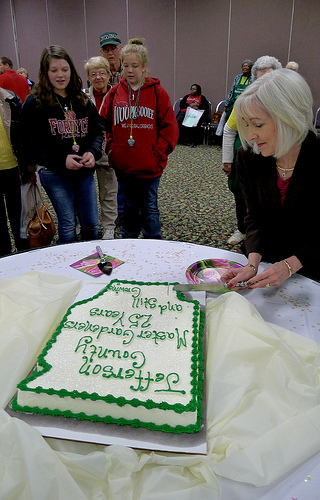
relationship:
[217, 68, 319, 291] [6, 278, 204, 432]
lady cutting cake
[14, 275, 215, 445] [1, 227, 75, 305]
cake on top of table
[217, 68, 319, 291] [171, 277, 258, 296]
lady holding knife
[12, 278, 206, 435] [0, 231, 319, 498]
cake on table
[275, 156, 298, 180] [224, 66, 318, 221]
necklace on woman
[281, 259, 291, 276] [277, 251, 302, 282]
bracelet on wrist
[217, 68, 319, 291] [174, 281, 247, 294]
lady holding knife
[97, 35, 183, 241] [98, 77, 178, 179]
girl in shirt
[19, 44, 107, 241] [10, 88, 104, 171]
girl in shirt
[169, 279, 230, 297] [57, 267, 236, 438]
knife above cake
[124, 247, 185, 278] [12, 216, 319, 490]
confetti on table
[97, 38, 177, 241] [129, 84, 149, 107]
girl wearing necklace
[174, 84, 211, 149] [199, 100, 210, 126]
lady sitting in chair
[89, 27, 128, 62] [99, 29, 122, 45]
man wearing hat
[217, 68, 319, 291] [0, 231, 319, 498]
lady standing around table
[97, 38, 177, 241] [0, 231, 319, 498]
girl standing around table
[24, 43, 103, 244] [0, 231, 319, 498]
person standing around table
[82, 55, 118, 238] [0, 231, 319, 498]
person standing around table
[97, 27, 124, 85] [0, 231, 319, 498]
man standing around table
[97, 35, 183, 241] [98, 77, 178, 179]
girl wearing shirt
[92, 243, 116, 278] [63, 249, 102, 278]
serving knife on top of napkin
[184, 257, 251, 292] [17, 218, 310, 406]
paper plate sitting on top table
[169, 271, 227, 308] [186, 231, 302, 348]
knife in hands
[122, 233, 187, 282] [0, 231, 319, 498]
cloth on table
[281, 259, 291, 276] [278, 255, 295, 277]
bracelet on wrist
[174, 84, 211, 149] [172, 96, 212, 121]
lady sitting in chair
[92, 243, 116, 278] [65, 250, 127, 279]
serving knife on napkin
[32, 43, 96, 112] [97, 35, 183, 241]
hair on girl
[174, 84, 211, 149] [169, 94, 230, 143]
lady sitting in chair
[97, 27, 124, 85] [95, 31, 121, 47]
man has green cap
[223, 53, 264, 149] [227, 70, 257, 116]
woman has shirt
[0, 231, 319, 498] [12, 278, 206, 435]
table has cake